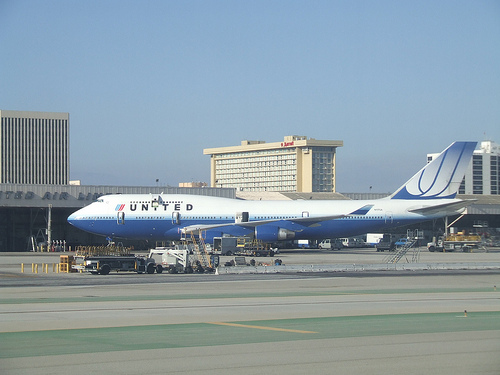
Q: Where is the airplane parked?
A: At the airport.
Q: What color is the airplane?
A: Blue and white.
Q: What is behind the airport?
A: A large building.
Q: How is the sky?
A: Clear and blue.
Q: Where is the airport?
A: Behind the airplane.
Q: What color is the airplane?
A: Blue and white.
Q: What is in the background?
A: A large building.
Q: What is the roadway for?
A: The airplane to land on.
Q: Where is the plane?
A: On the airport.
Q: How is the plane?
A: It is a big blue and white colored plane.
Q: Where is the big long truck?
A: Near the belly of the plane.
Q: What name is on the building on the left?
A: United Air Lines.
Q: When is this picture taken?
A: During daytime.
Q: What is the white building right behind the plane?
A: Marriott hotel.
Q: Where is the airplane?
A: On the tarmac.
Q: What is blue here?
A: The sky.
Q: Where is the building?
A: Behind the plane.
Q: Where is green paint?
A: On the ground.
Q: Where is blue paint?
A: On the plane.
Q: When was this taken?
A: Daytime.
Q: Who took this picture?
A: A photographer.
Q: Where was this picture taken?
A: Tarmac.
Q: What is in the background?
A: A building.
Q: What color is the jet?
A: Blue and White.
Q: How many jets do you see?
A: One.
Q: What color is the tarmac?
A: Green and black.